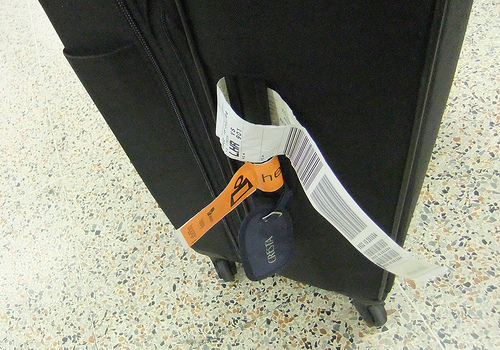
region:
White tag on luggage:
[220, 77, 447, 288]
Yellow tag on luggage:
[180, 160, 280, 254]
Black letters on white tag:
[226, 133, 240, 159]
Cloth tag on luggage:
[237, 209, 289, 280]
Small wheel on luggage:
[357, 299, 390, 324]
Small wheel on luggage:
[209, 260, 234, 279]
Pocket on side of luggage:
[55, 41, 235, 262]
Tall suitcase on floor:
[37, 3, 472, 346]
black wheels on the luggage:
[207, 237, 391, 335]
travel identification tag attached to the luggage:
[232, 196, 302, 285]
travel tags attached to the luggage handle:
[173, 82, 441, 291]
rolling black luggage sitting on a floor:
[35, 0, 479, 325]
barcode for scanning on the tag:
[282, 122, 408, 280]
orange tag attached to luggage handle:
[169, 158, 283, 252]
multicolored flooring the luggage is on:
[26, 140, 232, 348]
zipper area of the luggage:
[154, 8, 231, 219]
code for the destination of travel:
[224, 134, 245, 163]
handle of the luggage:
[219, 50, 296, 211]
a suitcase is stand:
[40, 2, 485, 329]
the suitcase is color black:
[36, 0, 476, 337]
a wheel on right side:
[339, 290, 391, 331]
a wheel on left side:
[205, 253, 242, 287]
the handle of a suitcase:
[223, 76, 291, 210]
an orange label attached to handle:
[169, 165, 282, 242]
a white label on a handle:
[211, 69, 448, 287]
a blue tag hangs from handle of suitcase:
[234, 189, 301, 290]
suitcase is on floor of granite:
[9, 6, 499, 346]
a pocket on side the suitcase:
[41, 23, 155, 111]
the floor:
[26, 247, 189, 312]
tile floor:
[21, 213, 185, 323]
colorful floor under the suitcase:
[35, 243, 208, 318]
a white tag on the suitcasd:
[200, 86, 426, 276]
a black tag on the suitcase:
[246, 205, 303, 307]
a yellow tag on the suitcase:
[165, 152, 295, 242]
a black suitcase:
[81, 45, 457, 321]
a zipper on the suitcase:
[140, 30, 197, 151]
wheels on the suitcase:
[357, 295, 383, 321]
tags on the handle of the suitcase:
[165, 73, 425, 280]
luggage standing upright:
[1, 2, 481, 327]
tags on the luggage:
[133, 83, 444, 298]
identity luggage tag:
[238, 198, 284, 286]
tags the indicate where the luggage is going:
[205, 86, 433, 281]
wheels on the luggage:
[200, 263, 400, 323]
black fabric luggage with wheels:
[40, 0, 452, 325]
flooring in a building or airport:
[15, 40, 485, 335]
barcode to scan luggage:
[280, 110, 320, 200]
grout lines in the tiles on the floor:
[17, 5, 107, 347]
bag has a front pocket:
[44, 38, 218, 265]